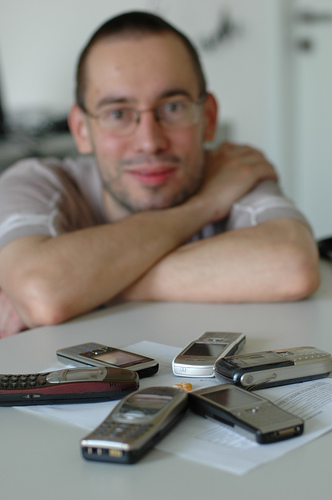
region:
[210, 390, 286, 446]
phone on the table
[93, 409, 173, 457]
phone on the table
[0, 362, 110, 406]
phone on the table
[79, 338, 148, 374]
phone on the table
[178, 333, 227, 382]
phone on the table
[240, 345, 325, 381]
phone on the table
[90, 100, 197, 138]
glasses on the man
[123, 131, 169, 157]
nose of the man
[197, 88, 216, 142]
ear of the man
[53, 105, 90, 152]
ear of the man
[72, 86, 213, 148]
glasses on man's face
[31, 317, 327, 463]
phones on a table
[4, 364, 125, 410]
black and red phone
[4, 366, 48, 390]
buttons on the phone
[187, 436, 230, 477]
paper under the phones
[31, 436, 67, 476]
white table under the phones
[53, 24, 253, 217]
man looking at the camera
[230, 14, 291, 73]
blurry background of the photo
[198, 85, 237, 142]
ear of the man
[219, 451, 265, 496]
corner of the paper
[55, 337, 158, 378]
a silver cell phone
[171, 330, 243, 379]
a silver cell phone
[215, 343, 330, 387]
a cordless flip phone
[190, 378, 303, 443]
a silver and black cell phone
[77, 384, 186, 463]
a silver and black cell phone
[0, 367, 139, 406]
a red and black cell phone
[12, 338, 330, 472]
a piece of paper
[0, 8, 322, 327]
a man resting arms on table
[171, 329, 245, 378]
a candy bar style phone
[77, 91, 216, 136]
a pair of eyeglasses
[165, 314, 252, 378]
a mobile hand set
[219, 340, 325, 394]
a mobile hand set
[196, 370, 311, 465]
a mobile hand set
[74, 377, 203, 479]
a mobile hand set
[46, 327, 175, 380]
a mobile hand set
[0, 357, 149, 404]
a mobile hand set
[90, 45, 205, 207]
Face of a person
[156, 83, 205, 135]
Eye of a person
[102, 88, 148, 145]
Eye of a person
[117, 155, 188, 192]
Mouth of a person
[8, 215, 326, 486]
The man has six cell phones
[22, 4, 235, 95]
The man has dark hair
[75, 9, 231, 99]
The man's hair is short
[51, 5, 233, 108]
The man's hair is straight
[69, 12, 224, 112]
The man's hair is brown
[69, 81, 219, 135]
The man is wearing glasses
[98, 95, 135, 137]
The man's eye is open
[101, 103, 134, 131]
The man's eye is brown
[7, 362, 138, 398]
The cell phone is red and black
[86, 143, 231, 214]
The man has a thin beard